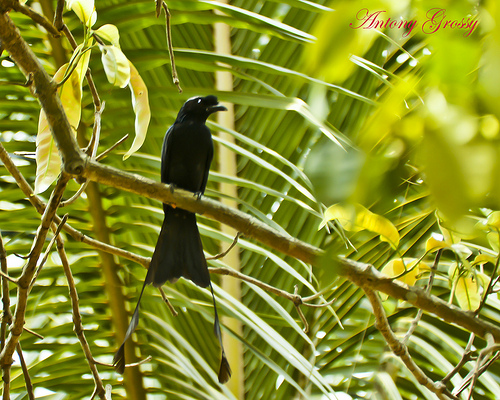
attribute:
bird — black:
[143, 94, 226, 286]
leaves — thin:
[323, 199, 415, 256]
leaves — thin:
[306, 24, 424, 88]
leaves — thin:
[233, 64, 333, 142]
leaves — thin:
[147, 313, 215, 398]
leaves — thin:
[413, 311, 465, 373]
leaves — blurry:
[308, 8, 481, 248]